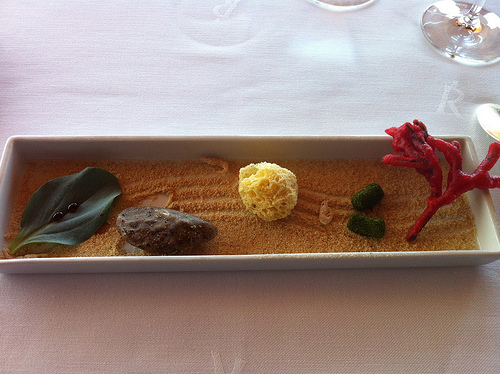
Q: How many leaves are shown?
A: One.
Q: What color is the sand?
A: Brown.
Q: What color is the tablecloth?
A: White.